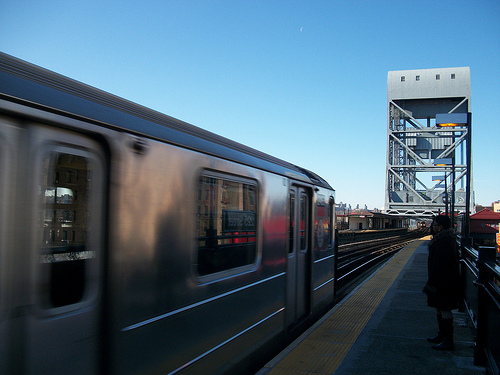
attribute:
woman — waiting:
[423, 215, 462, 350]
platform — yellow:
[250, 234, 472, 374]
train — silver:
[1, 52, 338, 374]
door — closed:
[3, 112, 109, 375]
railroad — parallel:
[334, 228, 429, 302]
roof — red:
[468, 219, 495, 230]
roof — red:
[467, 206, 499, 220]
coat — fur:
[425, 235, 460, 309]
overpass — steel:
[385, 208, 440, 217]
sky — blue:
[1, 1, 500, 210]